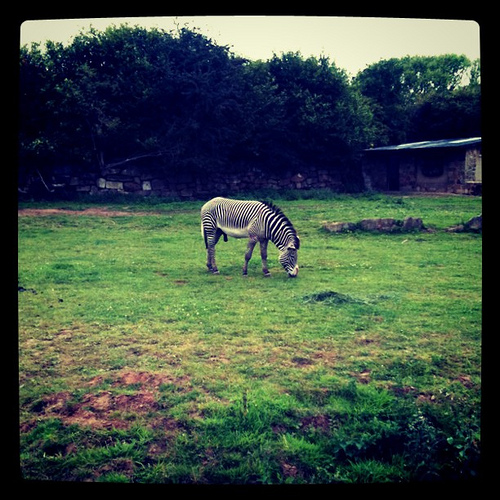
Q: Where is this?
A: This is at the field.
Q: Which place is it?
A: It is a field.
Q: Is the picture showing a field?
A: Yes, it is showing a field.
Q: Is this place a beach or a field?
A: It is a field.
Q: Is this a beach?
A: No, it is a field.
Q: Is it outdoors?
A: Yes, it is outdoors.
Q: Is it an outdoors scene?
A: Yes, it is outdoors.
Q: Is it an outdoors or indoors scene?
A: It is outdoors.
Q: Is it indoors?
A: No, it is outdoors.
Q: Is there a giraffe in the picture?
A: No, there are no giraffes.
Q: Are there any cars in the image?
A: No, there are no cars.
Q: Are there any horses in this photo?
A: No, there are no horses.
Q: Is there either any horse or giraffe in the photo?
A: No, there are no horses or giraffes.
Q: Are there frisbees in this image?
A: No, there are no frisbees.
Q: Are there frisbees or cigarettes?
A: No, there are no frisbees or cigarettes.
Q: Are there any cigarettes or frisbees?
A: No, there are no frisbees or cigarettes.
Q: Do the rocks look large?
A: Yes, the rocks are large.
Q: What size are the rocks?
A: The rocks are large.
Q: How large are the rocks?
A: The rocks are large.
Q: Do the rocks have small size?
A: No, the rocks are large.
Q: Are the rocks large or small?
A: The rocks are large.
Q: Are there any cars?
A: No, there are no cars.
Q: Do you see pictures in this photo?
A: No, there are no pictures.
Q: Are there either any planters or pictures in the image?
A: No, there are no pictures or planters.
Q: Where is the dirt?
A: The dirt is in the grass.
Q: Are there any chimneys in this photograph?
A: No, there are no chimneys.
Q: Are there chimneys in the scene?
A: No, there are no chimneys.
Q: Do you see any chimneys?
A: No, there are no chimneys.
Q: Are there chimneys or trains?
A: No, there are no chimneys or trains.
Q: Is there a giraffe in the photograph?
A: No, there are no giraffes.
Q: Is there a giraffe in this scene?
A: No, there are no giraffes.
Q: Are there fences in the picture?
A: Yes, there is a fence.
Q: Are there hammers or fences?
A: Yes, there is a fence.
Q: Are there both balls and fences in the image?
A: No, there is a fence but no balls.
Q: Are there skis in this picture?
A: No, there are no skis.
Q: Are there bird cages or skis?
A: No, there are no skis or bird cages.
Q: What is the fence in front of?
A: The fence is in front of the trees.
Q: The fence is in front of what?
A: The fence is in front of the trees.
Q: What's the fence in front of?
A: The fence is in front of the trees.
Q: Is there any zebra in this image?
A: Yes, there is a zebra.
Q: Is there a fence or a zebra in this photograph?
A: Yes, there is a zebra.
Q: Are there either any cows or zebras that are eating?
A: Yes, the zebra is eating.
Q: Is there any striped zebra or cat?
A: Yes, there is a striped zebra.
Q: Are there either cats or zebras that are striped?
A: Yes, the zebra is striped.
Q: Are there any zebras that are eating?
A: Yes, there is a zebra that is eating.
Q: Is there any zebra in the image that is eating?
A: Yes, there is a zebra that is eating.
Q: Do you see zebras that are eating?
A: Yes, there is a zebra that is eating.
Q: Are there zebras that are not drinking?
A: Yes, there is a zebra that is eating.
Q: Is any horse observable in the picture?
A: No, there are no horses.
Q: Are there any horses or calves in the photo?
A: No, there are no horses or calves.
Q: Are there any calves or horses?
A: No, there are no horses or calves.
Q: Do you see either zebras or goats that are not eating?
A: No, there is a zebra but it is eating.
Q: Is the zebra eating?
A: Yes, the zebra is eating.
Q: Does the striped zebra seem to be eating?
A: Yes, the zebra is eating.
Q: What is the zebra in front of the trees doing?
A: The zebra is eating.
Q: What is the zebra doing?
A: The zebra is eating.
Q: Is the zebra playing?
A: No, the zebra is eating.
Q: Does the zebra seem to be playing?
A: No, the zebra is eating.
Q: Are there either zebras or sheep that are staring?
A: No, there is a zebra but it is eating.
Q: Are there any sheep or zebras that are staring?
A: No, there is a zebra but it is eating.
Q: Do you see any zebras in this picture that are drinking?
A: No, there is a zebra but it is eating.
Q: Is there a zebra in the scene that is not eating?
A: No, there is a zebra but it is eating.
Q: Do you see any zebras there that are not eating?
A: No, there is a zebra but it is eating.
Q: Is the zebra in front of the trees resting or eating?
A: The zebra is eating.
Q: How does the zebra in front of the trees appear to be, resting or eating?
A: The zebra is eating.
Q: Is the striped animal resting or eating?
A: The zebra is eating.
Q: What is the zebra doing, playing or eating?
A: The zebra is eating.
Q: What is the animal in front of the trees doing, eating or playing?
A: The zebra is eating.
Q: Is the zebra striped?
A: Yes, the zebra is striped.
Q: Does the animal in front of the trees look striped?
A: Yes, the zebra is striped.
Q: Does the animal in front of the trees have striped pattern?
A: Yes, the zebra is striped.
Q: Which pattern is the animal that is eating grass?
A: The zebra is striped.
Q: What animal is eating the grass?
A: The zebra is eating the grass.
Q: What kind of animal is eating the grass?
A: The animal is a zebra.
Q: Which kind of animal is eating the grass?
A: The animal is a zebra.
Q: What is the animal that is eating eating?
A: The zebra is eating grass.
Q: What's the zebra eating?
A: The zebra is eating grass.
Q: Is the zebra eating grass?
A: Yes, the zebra is eating grass.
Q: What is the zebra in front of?
A: The zebra is in front of the trees.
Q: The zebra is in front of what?
A: The zebra is in front of the trees.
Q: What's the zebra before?
A: The zebra is in front of the trees.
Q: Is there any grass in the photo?
A: Yes, there is grass.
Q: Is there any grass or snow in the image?
A: Yes, there is grass.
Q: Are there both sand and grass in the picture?
A: No, there is grass but no sand.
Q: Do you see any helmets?
A: No, there are no helmets.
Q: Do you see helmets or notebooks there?
A: No, there are no helmets or notebooks.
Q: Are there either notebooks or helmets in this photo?
A: No, there are no helmets or notebooks.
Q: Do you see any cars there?
A: No, there are no cars.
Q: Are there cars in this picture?
A: No, there are no cars.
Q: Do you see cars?
A: No, there are no cars.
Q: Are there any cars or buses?
A: No, there are no cars or buses.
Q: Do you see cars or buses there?
A: No, there are no cars or buses.